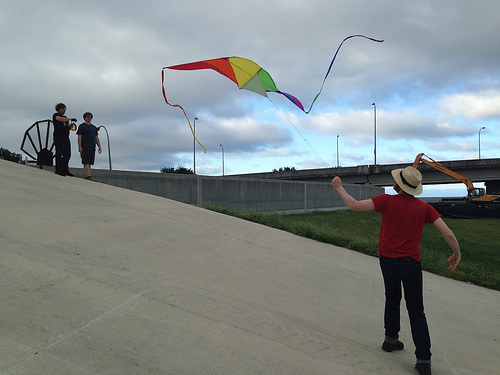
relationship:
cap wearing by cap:
[391, 166, 423, 195] [386, 164, 433, 194]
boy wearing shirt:
[332, 166, 460, 375] [371, 193, 441, 263]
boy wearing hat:
[332, 166, 460, 375] [389, 160, 425, 195]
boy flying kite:
[332, 166, 460, 375] [142, 43, 484, 367]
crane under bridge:
[412, 153, 500, 208] [340, 150, 482, 208]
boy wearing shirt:
[332, 166, 460, 375] [50, 109, 72, 143]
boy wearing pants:
[332, 166, 460, 375] [54, 133, 73, 166]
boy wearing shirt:
[332, 166, 460, 375] [73, 117, 103, 144]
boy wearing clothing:
[332, 166, 460, 375] [81, 146, 95, 165]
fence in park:
[81, 162, 386, 211] [0, 141, 482, 340]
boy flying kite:
[332, 166, 460, 375] [124, 29, 392, 141]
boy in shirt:
[332, 166, 460, 375] [368, 184, 441, 264]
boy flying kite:
[332, 166, 460, 375] [157, 30, 383, 141]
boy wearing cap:
[332, 166, 460, 375] [391, 166, 423, 195]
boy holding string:
[332, 166, 460, 375] [268, 101, 341, 173]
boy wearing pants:
[332, 166, 460, 375] [370, 255, 443, 353]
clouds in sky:
[3, 4, 165, 92] [7, 8, 465, 156]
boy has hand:
[332, 166, 460, 375] [327, 172, 342, 186]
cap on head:
[386, 164, 433, 194] [391, 162, 423, 192]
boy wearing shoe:
[332, 166, 460, 375] [413, 358, 433, 374]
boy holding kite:
[327, 159, 473, 374] [161, 34, 383, 153]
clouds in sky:
[3, 4, 165, 92] [0, 0, 499, 195]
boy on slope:
[332, 166, 460, 375] [1, 159, 498, 373]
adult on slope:
[76, 112, 101, 182] [1, 159, 498, 373]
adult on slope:
[53, 103, 77, 177] [1, 159, 498, 373]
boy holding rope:
[332, 166, 460, 375] [266, 97, 336, 177]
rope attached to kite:
[266, 97, 336, 177] [161, 34, 383, 153]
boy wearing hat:
[332, 166, 460, 375] [391, 165, 423, 195]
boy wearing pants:
[332, 166, 460, 375] [379, 255, 430, 364]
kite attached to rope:
[161, 34, 383, 153] [266, 97, 334, 176]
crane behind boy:
[413, 151, 499, 211] [332, 166, 460, 375]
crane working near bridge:
[412, 153, 500, 208] [221, 157, 499, 193]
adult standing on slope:
[76, 112, 101, 182] [1, 159, 498, 373]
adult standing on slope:
[52, 102, 77, 175] [1, 159, 498, 373]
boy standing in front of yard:
[332, 166, 460, 375] [198, 203, 498, 288]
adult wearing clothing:
[78, 110, 101, 182] [76, 121, 98, 166]